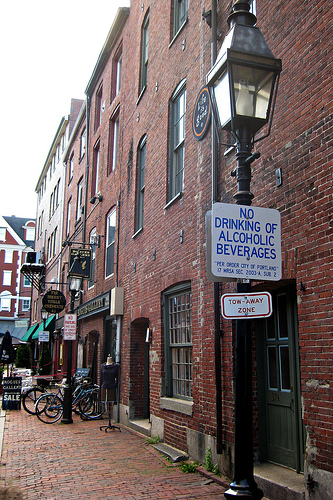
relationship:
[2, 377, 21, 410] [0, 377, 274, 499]
sign on sidewalk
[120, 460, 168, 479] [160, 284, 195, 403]
lines on window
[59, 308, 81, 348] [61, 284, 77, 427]
sign on pole